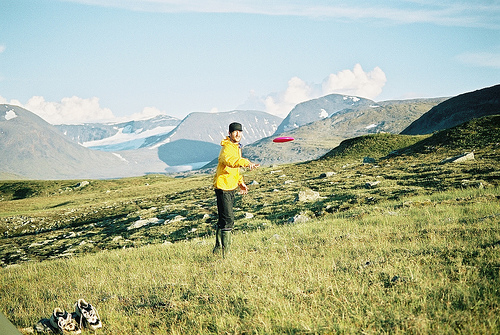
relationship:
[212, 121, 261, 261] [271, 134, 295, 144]
man throwing frisbee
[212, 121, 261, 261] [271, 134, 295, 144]
man playing frisbee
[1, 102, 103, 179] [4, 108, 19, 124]
mountain has snow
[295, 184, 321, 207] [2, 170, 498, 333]
rock in field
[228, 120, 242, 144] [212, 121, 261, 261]
head of man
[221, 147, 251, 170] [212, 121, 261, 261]
arm of man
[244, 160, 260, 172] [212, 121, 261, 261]
hand of man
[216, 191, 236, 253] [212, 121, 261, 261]
leg of man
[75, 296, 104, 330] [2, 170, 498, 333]
shoe in field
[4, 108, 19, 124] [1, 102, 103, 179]
snow on mountain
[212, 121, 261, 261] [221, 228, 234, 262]
man wearing boot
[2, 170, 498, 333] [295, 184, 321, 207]
field has rock